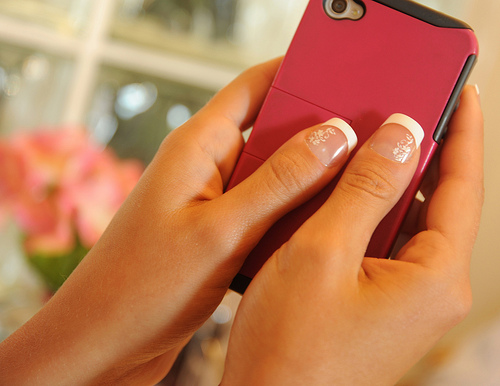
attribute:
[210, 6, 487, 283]
case — pink